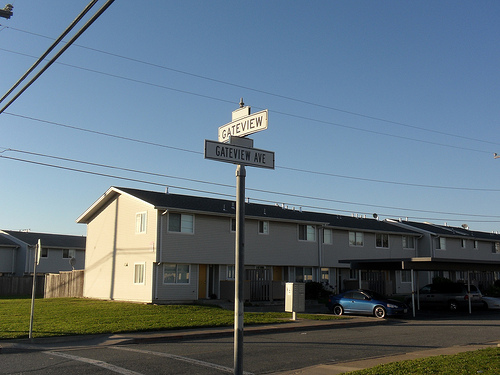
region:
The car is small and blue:
[326, 290, 417, 337]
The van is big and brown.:
[408, 269, 482, 316]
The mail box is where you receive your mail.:
[271, 271, 319, 336]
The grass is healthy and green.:
[1, 226, 160, 330]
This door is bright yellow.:
[180, 242, 231, 319]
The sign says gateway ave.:
[201, 87, 322, 218]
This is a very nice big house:
[48, 173, 498, 321]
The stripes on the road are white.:
[22, 313, 254, 374]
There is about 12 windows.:
[121, 210, 498, 265]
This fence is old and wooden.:
[0, 233, 92, 314]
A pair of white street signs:
[181, 76, 303, 373]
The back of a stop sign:
[23, 236, 45, 353]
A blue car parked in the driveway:
[319, 282, 424, 330]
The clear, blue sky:
[84, 6, 496, 182]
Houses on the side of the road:
[76, 147, 495, 337]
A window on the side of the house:
[159, 199, 210, 250]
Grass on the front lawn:
[3, 285, 294, 353]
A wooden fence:
[2, 264, 88, 305]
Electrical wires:
[4, 11, 496, 242]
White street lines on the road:
[33, 339, 257, 374]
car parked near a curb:
[317, 283, 413, 328]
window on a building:
[292, 217, 322, 247]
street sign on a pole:
[195, 88, 283, 180]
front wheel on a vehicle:
[369, 301, 389, 322]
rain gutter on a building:
[147, 203, 172, 303]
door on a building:
[194, 258, 224, 308]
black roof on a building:
[106, 178, 335, 230]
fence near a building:
[39, 265, 91, 304]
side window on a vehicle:
[337, 289, 374, 302]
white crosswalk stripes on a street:
[34, 338, 261, 374]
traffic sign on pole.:
[22, 237, 47, 337]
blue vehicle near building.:
[329, 292, 402, 319]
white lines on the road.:
[89, 345, 217, 369]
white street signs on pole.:
[197, 108, 281, 164]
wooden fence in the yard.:
[40, 265, 78, 292]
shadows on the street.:
[271, 335, 407, 351]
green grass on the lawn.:
[50, 303, 117, 320]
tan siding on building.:
[96, 217, 123, 287]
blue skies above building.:
[291, 140, 417, 152]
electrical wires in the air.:
[20, 144, 115, 176]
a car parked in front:
[320, 283, 402, 325]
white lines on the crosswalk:
[66, 343, 256, 373]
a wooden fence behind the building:
[4, 271, 81, 297]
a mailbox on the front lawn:
[284, 281, 308, 323]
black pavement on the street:
[261, 335, 332, 356]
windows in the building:
[161, 209, 204, 236]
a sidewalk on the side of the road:
[331, 349, 440, 365]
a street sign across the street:
[203, 95, 275, 372]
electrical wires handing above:
[17, 10, 119, 56]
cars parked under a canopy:
[423, 271, 495, 314]